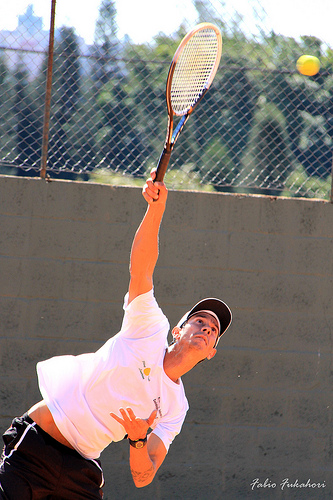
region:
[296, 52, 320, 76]
Yellow tennis ball in the air.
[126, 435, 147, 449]
Black watch on man's wrist.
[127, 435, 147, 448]
Man wearing a wrist watch.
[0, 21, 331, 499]
Man playing tennis on court.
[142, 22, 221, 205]
Tennis racket in man's right hand.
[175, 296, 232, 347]
White and black cap on tennis player's head.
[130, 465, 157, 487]
Tattoos on the man's arm.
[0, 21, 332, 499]
Tennis player attempting to hit the ball.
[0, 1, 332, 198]
Metal fence securing the tennis court.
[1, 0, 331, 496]
Gray wall and wire fence.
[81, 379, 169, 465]
Person wearing white shirt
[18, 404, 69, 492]
Person wearing black shorts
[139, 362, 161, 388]
Yellow design on shirt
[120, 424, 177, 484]
Man is wearing black watch on wrist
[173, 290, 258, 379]
Man wearing white hat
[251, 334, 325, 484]
Gray wall behind man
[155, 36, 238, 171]
Man swinging tennis racquet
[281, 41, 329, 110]
Tennis ball is greenish yelllow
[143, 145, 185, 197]
Grip on racquet is black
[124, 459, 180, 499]
Tattoo on man's forearm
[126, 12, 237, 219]
tennis racket held up in the air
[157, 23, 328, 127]
tennis ball close to strings of racket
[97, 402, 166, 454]
black watch on a player's wrist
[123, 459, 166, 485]
tattoo designs near an elbow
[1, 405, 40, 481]
white stripe on the side of black shorts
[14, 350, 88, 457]
t-shirt hem rising to reveal midriff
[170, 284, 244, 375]
eyes lifted underneath a cap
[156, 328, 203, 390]
neck extended from white shirt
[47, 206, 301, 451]
painted grey surface of wall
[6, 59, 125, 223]
chain-link fence on top of wall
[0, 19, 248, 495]
a man holding a tennis racket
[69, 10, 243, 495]
a man playing tennis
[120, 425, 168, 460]
a black watch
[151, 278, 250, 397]
a man wearing a hat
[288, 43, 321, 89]
a yellow tennis ball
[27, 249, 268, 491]
a man wearing a white shirt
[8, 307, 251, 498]
a man wearing black bottoms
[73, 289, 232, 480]
a man wearing a watch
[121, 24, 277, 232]
a tennis racket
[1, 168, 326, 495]
silver cement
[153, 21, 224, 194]
Tennis racket being swung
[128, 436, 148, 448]
Black watch on a man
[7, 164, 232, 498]
A man that is playing tennis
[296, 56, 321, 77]
A yellow tennis ball going through the air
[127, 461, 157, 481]
A tattoo on a man's arm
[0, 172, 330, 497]
A cement block wall at a tennis court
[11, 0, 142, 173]
Chain link fence surrounding tennis court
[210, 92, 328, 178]
Evergreen trees beyond a tennis court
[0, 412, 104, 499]
Black shorts on a tennis player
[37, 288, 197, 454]
White shirt on a tennis player